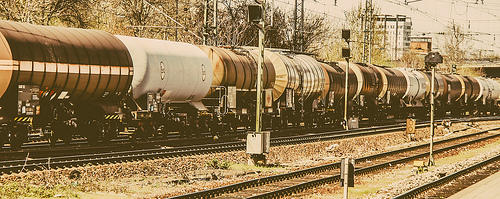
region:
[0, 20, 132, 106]
The tank is brown.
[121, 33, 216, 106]
The tank is white.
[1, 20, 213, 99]
The brown tank is besides the white tank.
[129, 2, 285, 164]
The light pole is in front of the white tank.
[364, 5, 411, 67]
The tree is next to the building.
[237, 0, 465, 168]
Three light poles are next to each other.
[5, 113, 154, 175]
The wheels are touching the train tracks.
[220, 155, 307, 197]
The grass is next to the train tracks.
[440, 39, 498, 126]
The train is going inside of the tunnel.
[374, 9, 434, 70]
The white building is next to the buildboard.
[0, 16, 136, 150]
first train car on the tracks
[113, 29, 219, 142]
second train car on the tracks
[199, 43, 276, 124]
third train car on the tracks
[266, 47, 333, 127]
fourth train car on the tracks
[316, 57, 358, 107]
fifth train car on the tracks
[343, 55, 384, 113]
sixth train car on the tracks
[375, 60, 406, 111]
seventh train car on the tracks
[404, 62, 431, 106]
eighth train car on the tracks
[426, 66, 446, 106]
ninth train car on the tracks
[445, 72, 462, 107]
tenth train car on the tracks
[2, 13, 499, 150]
commercial material train cars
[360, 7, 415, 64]
multi story white building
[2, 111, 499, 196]
rusty metal train tracks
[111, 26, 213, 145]
white cylindrical train car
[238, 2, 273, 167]
rail road signal sign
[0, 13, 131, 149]
black cylindrical train car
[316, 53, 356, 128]
black cylindrical train car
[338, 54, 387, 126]
black cylindrical train car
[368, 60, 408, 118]
black cylindrical train car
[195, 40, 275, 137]
black cylindrical train car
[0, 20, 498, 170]
train is on the tracks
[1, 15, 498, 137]
train is carrying a long load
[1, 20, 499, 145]
train is sitting on the railroad tracks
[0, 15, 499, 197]
emptying tracks are next to the train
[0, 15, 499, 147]
train is headed into town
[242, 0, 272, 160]
the pole is next to the train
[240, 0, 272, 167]
the pole is next to the tracks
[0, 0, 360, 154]
train is next to two poles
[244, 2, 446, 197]
the poles and signs are used by the trains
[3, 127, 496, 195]
the tracks are next to the poles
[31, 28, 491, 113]
a long train in track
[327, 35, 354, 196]
a long electric poll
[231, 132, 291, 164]
a small object in the poll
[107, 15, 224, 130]
a white object in train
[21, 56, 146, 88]
a white line train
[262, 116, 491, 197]
a long rail way track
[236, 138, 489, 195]
two rail way track beside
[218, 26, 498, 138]
a group of electric signals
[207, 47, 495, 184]
three poles in the track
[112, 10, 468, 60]
a part of trees